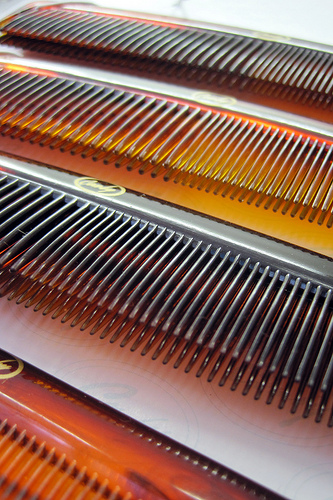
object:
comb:
[0, 163, 328, 425]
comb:
[0, 4, 332, 115]